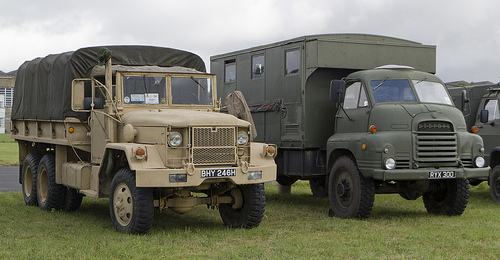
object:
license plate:
[201, 168, 236, 177]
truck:
[10, 44, 277, 233]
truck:
[209, 32, 491, 218]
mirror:
[330, 79, 345, 104]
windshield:
[122, 76, 166, 104]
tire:
[109, 169, 154, 234]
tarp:
[11, 44, 207, 118]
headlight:
[168, 132, 182, 147]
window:
[285, 49, 301, 75]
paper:
[145, 93, 159, 105]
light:
[136, 148, 145, 156]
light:
[266, 146, 276, 155]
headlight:
[237, 131, 249, 145]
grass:
[3, 204, 197, 258]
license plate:
[429, 171, 456, 178]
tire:
[327, 154, 374, 220]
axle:
[153, 190, 243, 213]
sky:
[0, 1, 498, 84]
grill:
[192, 128, 236, 166]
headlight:
[386, 157, 396, 169]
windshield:
[371, 78, 453, 104]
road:
[2, 165, 25, 192]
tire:
[37, 155, 66, 210]